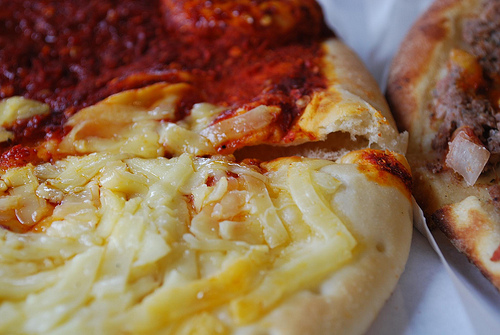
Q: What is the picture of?
A: Pizza.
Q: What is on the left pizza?
A: Cheese.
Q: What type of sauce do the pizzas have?
A: Red sauce.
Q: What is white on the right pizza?
A: Onion.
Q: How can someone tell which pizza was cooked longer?
A: Darker crust.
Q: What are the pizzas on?
A: Paper.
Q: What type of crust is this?
A: Pan.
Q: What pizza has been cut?
A: Left.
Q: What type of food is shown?
A: Pizza.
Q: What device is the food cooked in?
A: An oven.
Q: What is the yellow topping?
A: Cheese.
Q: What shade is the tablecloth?
A: White.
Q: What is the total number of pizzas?
A: 2.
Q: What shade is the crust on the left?
A: White.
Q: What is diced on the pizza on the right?
A: Onions.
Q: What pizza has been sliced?
A: The left one.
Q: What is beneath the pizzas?
A: A tablecloth.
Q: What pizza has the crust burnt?
A: The right one.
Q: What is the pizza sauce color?
A: Red.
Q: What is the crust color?
A: White.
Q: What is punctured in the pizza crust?
A: Holes.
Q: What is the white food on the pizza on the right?
A: Onion.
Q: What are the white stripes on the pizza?
A: Cheese.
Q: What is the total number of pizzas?
A: 2.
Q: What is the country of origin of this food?
A: Italy.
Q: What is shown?
A: Food.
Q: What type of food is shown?
A: Pizza.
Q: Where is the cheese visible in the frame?
A: Bottom left.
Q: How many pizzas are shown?
A: Two.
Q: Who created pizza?
A: Italians.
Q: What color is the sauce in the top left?
A: Red.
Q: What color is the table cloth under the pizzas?
A: White.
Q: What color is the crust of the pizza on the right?
A: Brown.